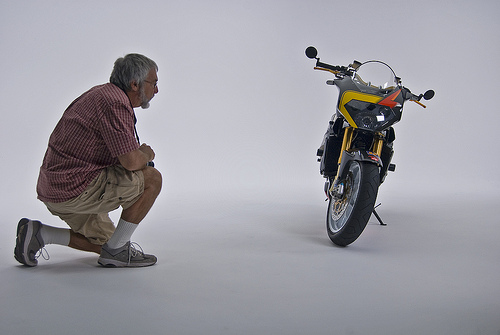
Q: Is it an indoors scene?
A: Yes, it is indoors.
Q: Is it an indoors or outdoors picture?
A: It is indoors.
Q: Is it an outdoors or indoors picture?
A: It is indoors.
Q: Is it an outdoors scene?
A: No, it is indoors.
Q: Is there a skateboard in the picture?
A: No, there are no skateboards.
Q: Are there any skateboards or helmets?
A: No, there are no skateboards or helmets.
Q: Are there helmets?
A: No, there are no helmets.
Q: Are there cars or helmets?
A: No, there are no helmets or cars.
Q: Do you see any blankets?
A: No, there are no blankets.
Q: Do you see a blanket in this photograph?
A: No, there are no blankets.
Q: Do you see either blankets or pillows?
A: No, there are no blankets or pillows.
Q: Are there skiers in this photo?
A: No, there are no skiers.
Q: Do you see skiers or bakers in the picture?
A: No, there are no skiers or bakers.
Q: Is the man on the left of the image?
A: Yes, the man is on the left of the image.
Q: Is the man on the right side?
A: No, the man is on the left of the image.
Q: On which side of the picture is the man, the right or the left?
A: The man is on the left of the image.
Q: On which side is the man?
A: The man is on the left of the image.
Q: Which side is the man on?
A: The man is on the left of the image.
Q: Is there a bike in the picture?
A: Yes, there is a bike.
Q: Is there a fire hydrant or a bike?
A: Yes, there is a bike.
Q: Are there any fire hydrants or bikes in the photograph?
A: Yes, there is a bike.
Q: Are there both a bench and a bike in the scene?
A: No, there is a bike but no benches.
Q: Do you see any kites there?
A: No, there are no kites.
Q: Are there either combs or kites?
A: No, there are no kites or combs.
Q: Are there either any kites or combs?
A: No, there are no kites or combs.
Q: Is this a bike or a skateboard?
A: This is a bike.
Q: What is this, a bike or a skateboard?
A: This is a bike.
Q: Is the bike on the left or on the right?
A: The bike is on the right of the image.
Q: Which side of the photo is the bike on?
A: The bike is on the right of the image.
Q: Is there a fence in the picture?
A: No, there are no fences.